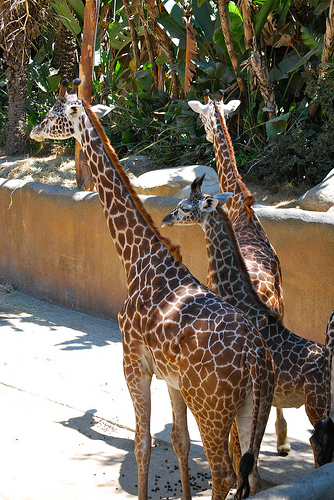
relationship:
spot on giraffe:
[215, 348, 248, 366] [28, 77, 274, 497]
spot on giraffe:
[201, 348, 212, 363] [20, 101, 323, 432]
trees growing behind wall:
[107, 2, 179, 125] [1, 175, 323, 339]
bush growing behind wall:
[249, 103, 333, 181] [1, 175, 323, 339]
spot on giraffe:
[192, 328, 212, 352] [28, 77, 274, 497]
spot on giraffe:
[108, 212, 129, 232] [28, 77, 274, 497]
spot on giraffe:
[163, 294, 202, 329] [34, 88, 204, 411]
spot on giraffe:
[233, 281, 243, 288] [158, 169, 330, 496]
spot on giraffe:
[213, 262, 234, 283] [151, 163, 331, 458]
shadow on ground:
[61, 398, 212, 498] [1, 285, 332, 496]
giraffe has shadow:
[28, 77, 274, 497] [61, 398, 212, 498]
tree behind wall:
[0, 2, 44, 148] [0, 178, 330, 316]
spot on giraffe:
[122, 224, 136, 247] [32, 98, 309, 490]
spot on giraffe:
[288, 365, 300, 380] [158, 169, 330, 496]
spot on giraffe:
[158, 314, 178, 338] [28, 77, 274, 497]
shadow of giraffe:
[53, 408, 212, 499] [28, 77, 274, 497]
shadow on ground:
[53, 332, 110, 354] [0, 293, 250, 494]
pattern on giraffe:
[111, 235, 226, 420] [28, 77, 274, 497]